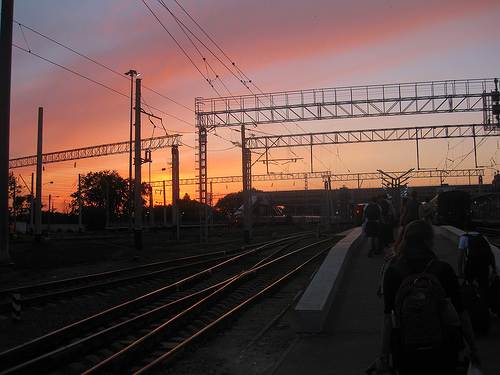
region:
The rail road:
[44, 283, 104, 326]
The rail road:
[170, 328, 208, 363]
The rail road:
[161, 283, 260, 368]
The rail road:
[143, 326, 200, 371]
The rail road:
[110, 253, 217, 369]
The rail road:
[138, 255, 200, 332]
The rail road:
[168, 345, 193, 369]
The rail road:
[121, 317, 188, 370]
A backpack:
[373, 246, 422, 340]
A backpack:
[343, 162, 491, 370]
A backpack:
[308, 138, 432, 353]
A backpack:
[338, 274, 454, 371]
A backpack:
[328, 288, 460, 320]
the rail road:
[121, 240, 210, 332]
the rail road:
[121, 270, 190, 355]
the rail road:
[153, 253, 210, 373]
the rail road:
[81, 307, 179, 372]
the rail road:
[97, 278, 236, 368]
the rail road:
[162, 261, 262, 372]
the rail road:
[166, 326, 243, 371]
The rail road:
[84, 309, 216, 370]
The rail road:
[138, 294, 198, 359]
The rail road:
[46, 233, 206, 363]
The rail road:
[175, 328, 237, 368]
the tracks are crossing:
[188, 246, 258, 311]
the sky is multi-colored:
[52, 114, 238, 186]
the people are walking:
[362, 186, 464, 327]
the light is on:
[122, 59, 159, 83]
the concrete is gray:
[292, 275, 328, 332]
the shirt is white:
[457, 230, 489, 246]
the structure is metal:
[185, 75, 497, 122]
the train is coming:
[227, 210, 329, 224]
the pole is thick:
[25, 105, 52, 232]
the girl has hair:
[408, 235, 425, 251]